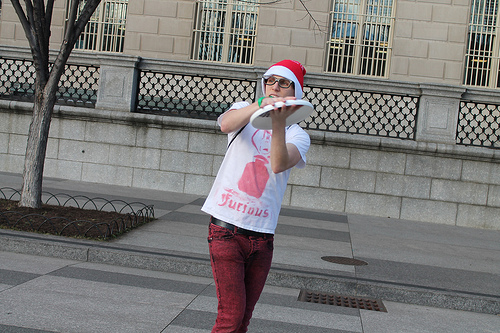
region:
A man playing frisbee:
[205, 42, 318, 332]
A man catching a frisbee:
[207, 51, 313, 331]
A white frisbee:
[252, 97, 315, 132]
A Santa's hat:
[261, 52, 321, 98]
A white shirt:
[205, 99, 308, 234]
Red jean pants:
[200, 212, 285, 330]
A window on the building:
[195, 2, 264, 66]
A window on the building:
[327, 2, 407, 80]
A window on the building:
[464, 1, 499, 90]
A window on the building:
[62, 0, 136, 55]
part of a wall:
[423, 196, 440, 211]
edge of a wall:
[347, 169, 352, 180]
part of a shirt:
[231, 193, 237, 201]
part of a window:
[358, 53, 368, 72]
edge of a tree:
[33, 111, 42, 128]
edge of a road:
[368, 260, 389, 280]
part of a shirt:
[226, 185, 231, 194]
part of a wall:
[439, 209, 457, 227]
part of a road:
[358, 258, 374, 273]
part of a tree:
[33, 148, 49, 171]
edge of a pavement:
[346, 265, 373, 285]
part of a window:
[352, 46, 364, 58]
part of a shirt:
[235, 218, 242, 228]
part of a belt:
[231, 224, 237, 230]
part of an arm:
[272, 146, 278, 158]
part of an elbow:
[276, 139, 281, 148]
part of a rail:
[338, 300, 346, 314]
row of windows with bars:
[62, 4, 494, 87]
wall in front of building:
[0, 43, 498, 228]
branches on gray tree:
[8, 1, 103, 208]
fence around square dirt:
[2, 187, 153, 244]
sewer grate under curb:
[299, 282, 389, 314]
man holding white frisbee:
[197, 60, 312, 328]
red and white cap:
[262, 58, 309, 108]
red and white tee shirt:
[203, 103, 310, 234]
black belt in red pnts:
[204, 214, 276, 331]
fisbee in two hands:
[222, 95, 314, 171]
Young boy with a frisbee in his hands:
[200, 56, 310, 331]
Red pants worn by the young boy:
[205, 212, 273, 329]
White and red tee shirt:
[198, 95, 308, 233]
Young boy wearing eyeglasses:
[255, 70, 293, 90]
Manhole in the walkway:
[320, 251, 370, 266]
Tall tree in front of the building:
[7, 0, 109, 206]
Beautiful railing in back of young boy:
[0, 42, 496, 158]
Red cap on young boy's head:
[270, 56, 305, 91]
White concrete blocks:
[0, 113, 496, 228]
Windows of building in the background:
[59, 1, 497, 91]